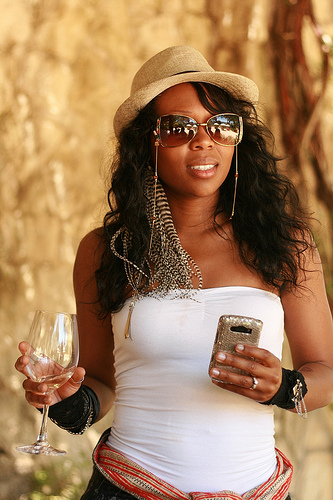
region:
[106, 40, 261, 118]
woman wearing a hat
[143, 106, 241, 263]
woman wearing sunglasses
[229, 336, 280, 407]
woman wearing a ring on the third finger of her left hand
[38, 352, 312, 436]
women wearing thick wristbands with metal detail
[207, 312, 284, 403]
woman holding a cell phone with her left hand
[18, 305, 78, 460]
woman holding a wine glass with a small amount of liquid in it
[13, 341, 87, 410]
ring on woman's right thumb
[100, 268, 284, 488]
woman wearing a tube top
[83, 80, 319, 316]
woman has long wavy black hair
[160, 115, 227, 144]
people reflected in woman's sunglasses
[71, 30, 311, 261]
woman with sunglasses on face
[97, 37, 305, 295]
lady with sunglasses on face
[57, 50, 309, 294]
person with long hair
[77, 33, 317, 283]
female person with sunglasses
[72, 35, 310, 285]
attractive lady wearing sunglasses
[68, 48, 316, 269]
attractive woman wearing sunglasses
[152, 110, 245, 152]
pair of large sunglasses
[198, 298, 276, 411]
hand holding a cell phone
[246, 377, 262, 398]
ring on person's finger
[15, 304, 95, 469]
hand holding a wine glass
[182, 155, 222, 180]
the mouth of a woman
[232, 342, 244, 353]
the fingernail of a woman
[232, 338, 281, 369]
the finger of a woman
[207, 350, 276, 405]
the hand of a woman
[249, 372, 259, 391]
a ring on the finger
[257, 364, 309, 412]
a black wrist band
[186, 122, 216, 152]
the nose of a woman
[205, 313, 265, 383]
a gray cell phone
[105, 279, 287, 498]
a white tube top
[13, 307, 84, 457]
a wine glass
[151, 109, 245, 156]
The sunglasses of the woman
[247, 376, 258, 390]
The woman's wedding ring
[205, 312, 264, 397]
The woman's cell phone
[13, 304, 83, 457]
The glass the woman is holding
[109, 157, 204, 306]
The feathers the woman is wearing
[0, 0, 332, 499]
The wall behind the woman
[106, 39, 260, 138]
The hat the woman's wearing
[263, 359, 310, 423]
The woman's left bracelet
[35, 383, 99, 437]
The woman's right bracelet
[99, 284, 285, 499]
The woman's white shirt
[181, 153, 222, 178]
the mouth of the woman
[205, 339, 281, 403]
the hand of the woman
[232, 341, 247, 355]
the nail on the woman's finger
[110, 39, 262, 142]
a brown straw hat